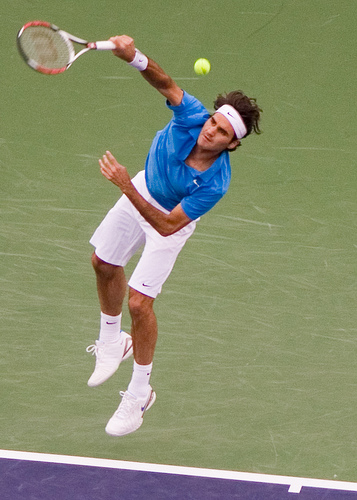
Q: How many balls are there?
A: One.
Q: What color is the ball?
A: Green.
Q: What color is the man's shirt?
A: Blue.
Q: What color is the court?
A: Blue and green.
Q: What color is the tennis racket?
A: White and red.